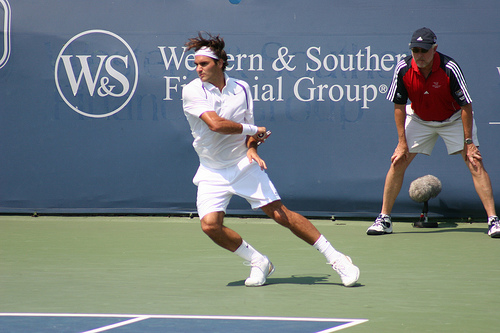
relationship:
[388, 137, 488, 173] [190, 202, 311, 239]
hands on knees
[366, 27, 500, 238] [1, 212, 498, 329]
ball boy standing on back of court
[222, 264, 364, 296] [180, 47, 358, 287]
shadow from man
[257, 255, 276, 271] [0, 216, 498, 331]
heel lifted off ground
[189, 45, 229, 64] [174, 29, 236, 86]
band around head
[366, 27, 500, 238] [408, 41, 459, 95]
ball boy in shirt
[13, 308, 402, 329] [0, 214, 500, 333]
lines outline court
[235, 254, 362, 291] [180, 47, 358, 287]
shoes on man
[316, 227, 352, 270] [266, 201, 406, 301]
sock on feet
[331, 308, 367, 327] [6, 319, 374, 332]
edge on court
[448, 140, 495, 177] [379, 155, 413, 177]
hand on knee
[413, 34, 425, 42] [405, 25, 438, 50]
logo on cap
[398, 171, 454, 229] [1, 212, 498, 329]
microphone on court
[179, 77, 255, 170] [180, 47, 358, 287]
t shirt on man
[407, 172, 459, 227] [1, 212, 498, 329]
thing on court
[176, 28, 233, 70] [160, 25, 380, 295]
hair on man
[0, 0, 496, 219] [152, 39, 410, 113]
wall with writing